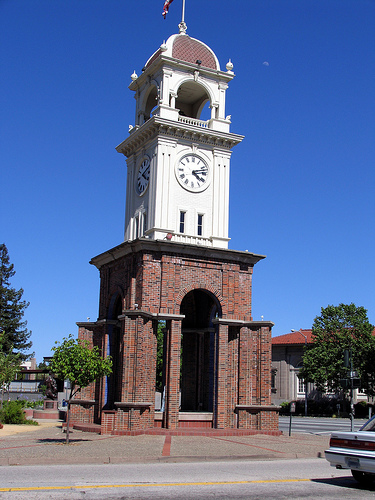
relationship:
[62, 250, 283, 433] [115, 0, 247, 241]
base on tower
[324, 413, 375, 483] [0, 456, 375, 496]
car on road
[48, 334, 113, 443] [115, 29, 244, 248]
bush near tower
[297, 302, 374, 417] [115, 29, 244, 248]
tree near tower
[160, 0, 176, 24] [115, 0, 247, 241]
flag on top of tower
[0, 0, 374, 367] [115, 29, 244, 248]
sky behind tower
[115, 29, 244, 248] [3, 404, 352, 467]
tower on corner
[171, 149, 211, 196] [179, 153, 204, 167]
clock with numerals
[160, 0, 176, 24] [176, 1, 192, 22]
flag on pole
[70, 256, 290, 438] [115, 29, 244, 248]
base of tower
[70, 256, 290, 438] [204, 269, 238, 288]
base made of brick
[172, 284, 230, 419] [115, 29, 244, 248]
doorway in tower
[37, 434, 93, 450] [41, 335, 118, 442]
shadow of tree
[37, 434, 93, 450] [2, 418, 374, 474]
shadow on ground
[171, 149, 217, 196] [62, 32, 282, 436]
clock on building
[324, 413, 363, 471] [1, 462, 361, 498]
car on road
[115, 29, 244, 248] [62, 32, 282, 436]
tower on building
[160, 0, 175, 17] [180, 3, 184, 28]
flag on pole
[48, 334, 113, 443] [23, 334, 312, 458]
bush in forefront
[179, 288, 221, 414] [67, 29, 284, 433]
opening in structure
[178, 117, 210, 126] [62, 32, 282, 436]
railing on building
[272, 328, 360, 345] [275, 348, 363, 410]
roof on building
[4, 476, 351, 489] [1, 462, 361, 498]
line on road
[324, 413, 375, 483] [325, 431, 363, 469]
car has rear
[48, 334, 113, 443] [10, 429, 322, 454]
bush planted in sidewalk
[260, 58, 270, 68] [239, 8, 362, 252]
moon in sky